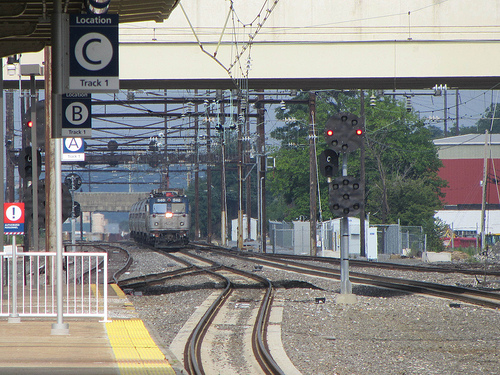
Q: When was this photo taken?
A: During the daytime.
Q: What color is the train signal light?
A: Red.